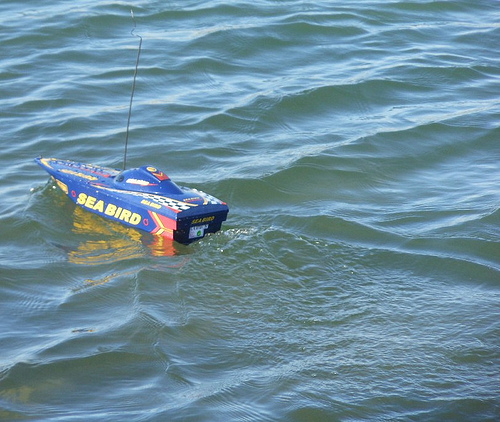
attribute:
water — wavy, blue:
[1, 0, 499, 419]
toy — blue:
[37, 150, 232, 247]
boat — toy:
[24, 30, 249, 249]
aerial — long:
[113, 8, 153, 167]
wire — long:
[112, 7, 149, 177]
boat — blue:
[21, 28, 300, 243]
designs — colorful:
[140, 187, 228, 245]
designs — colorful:
[41, 145, 114, 178]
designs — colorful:
[72, 188, 143, 225]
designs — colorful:
[126, 161, 170, 183]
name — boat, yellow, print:
[70, 189, 143, 229]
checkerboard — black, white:
[143, 186, 190, 209]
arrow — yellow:
[154, 211, 162, 240]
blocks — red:
[148, 210, 178, 239]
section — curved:
[110, 158, 188, 203]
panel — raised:
[110, 160, 180, 188]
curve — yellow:
[38, 150, 62, 167]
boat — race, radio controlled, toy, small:
[31, 18, 231, 247]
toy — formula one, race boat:
[27, 11, 238, 243]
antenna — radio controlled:
[116, 10, 144, 171]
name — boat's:
[75, 191, 142, 228]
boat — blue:
[31, 140, 237, 240]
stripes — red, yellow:
[149, 200, 183, 241]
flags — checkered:
[195, 180, 228, 215]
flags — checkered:
[155, 190, 196, 218]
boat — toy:
[28, 106, 251, 244]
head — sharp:
[26, 145, 83, 192]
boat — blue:
[10, 139, 251, 280]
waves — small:
[78, 259, 185, 373]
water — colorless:
[208, 77, 415, 389]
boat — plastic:
[12, 130, 242, 268]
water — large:
[47, 15, 490, 418]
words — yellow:
[68, 186, 148, 231]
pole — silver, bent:
[121, 26, 159, 55]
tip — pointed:
[130, 30, 162, 68]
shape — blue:
[112, 157, 181, 202]